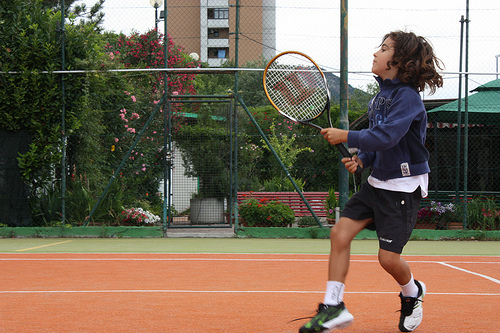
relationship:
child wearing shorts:
[298, 30, 445, 333] [324, 172, 420, 252]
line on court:
[45, 252, 385, 304] [26, 168, 463, 319]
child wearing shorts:
[298, 30, 445, 333] [338, 155, 428, 258]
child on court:
[298, 30, 445, 333] [4, 227, 484, 327]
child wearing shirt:
[298, 30, 445, 333] [357, 164, 430, 199]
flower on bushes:
[109, 85, 149, 146] [66, 63, 159, 223]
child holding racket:
[299, 32, 442, 328] [263, 51, 367, 178]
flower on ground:
[130, 205, 158, 222] [4, 216, 484, 241]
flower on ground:
[112, 208, 145, 225] [4, 216, 484, 241]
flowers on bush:
[244, 193, 279, 221] [239, 191, 291, 225]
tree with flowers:
[64, 34, 171, 222] [103, 84, 178, 193]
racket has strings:
[261, 48, 356, 171] [264, 52, 324, 121]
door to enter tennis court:
[162, 95, 234, 232] [0, 232, 500, 329]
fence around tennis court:
[7, 66, 498, 235] [0, 232, 500, 329]